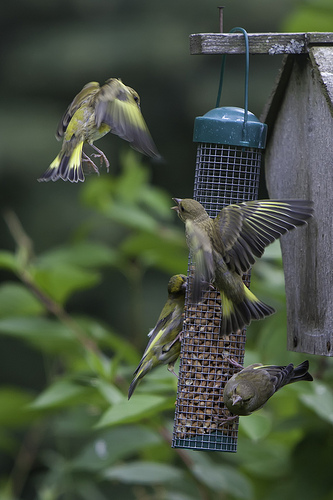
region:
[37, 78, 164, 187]
yellow and blue bird in flight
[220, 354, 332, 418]
green and gray bird feeding on bird feeder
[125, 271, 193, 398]
yellow and black bird feeding on bird feeder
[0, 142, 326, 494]
green leaves in the background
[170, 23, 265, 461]
green mesh wire bird feeder with food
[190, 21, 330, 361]
wooden bird house holding feeder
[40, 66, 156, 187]
bird flying in the air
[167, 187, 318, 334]
bird squawking at the other bird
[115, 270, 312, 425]
birds perched on the feeder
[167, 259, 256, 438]
bird seeds in the feeder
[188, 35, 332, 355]
wood birdhouse beside birds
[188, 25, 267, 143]
green top of the bird feeder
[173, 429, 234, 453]
green base of the feeder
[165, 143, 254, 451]
wire wrapped around bird feeder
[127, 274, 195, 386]
grey and yellow bird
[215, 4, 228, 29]
rusty nail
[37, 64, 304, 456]
canary birds around a feeder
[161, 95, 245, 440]
a green bird feeder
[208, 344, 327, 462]
a yellow and black bird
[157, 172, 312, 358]
yellow and black bird with mouth open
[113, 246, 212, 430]
a canary eating seeds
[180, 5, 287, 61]
a nail holding bird feeder on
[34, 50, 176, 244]
a bird coming in to eat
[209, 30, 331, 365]
a wooden bird house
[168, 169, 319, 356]
a yellow and black bird taking off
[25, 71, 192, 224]
bird with feet out to land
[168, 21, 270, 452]
cylindrical bird feeder of plastic and wire mesh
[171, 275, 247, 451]
brown seeds contained inside feeder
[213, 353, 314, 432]
greenish-brown bird with legs out to side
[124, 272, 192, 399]
gray and yellow bird pecking through feeder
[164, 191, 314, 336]
angry bird with open beak, open wing and open tail feathers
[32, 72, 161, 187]
bird with legs hanging and partial wing spread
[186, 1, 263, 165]
feeder hanging from wood stick behind nail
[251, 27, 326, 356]
wooden birdhouse behind wing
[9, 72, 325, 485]
green leaves and red stems behind birds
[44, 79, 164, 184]
The humming bird flying in the air.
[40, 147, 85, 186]
The tail feathers of the bird in the air.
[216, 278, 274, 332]
The tail feathers of the bird in the middle of the feeder.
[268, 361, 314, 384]
The tail feathers of the bird near the bottom of the feeder.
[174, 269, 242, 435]
The bird food in the feeder.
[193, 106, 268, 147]
The green top of the feeder.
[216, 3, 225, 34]
The rusted nail on the post.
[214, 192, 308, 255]
The expanded wing of the bird near the top of the feeder.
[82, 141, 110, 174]
The legs of the bird flying in the air.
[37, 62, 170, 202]
a bird in midair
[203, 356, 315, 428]
a bird standing sideways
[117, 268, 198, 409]
a bird hanging upright